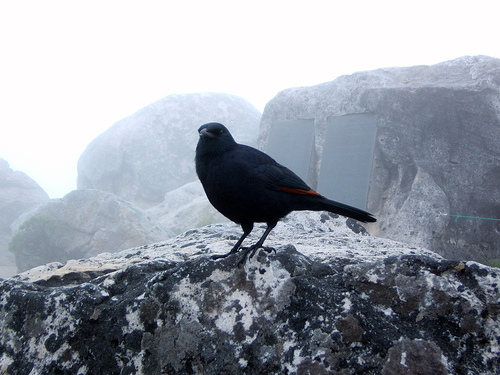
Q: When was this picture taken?
A: Daytime.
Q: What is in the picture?
A: A bird.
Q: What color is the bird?
A: Black.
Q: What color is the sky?
A: White.